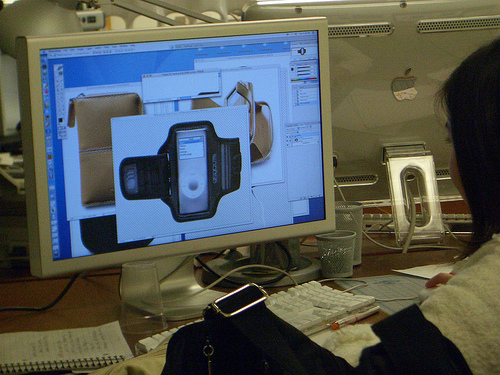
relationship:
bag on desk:
[157, 274, 347, 375] [13, 246, 482, 371]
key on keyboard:
[308, 301, 334, 323] [132, 274, 365, 374]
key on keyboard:
[327, 302, 351, 319] [141, 279, 389, 370]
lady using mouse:
[320, 34, 499, 375] [409, 279, 447, 305]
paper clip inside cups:
[324, 243, 354, 272] [316, 224, 360, 283]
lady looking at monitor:
[320, 34, 499, 375] [16, 29, 332, 258]